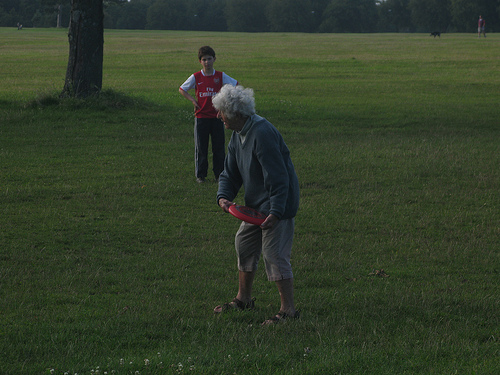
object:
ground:
[1, 32, 492, 375]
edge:
[264, 274, 294, 286]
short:
[233, 213, 294, 284]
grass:
[297, 32, 499, 163]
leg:
[259, 220, 301, 326]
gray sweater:
[216, 121, 296, 221]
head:
[210, 82, 259, 132]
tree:
[58, 1, 107, 100]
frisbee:
[223, 203, 265, 227]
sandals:
[207, 299, 299, 326]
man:
[203, 82, 304, 325]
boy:
[178, 45, 241, 184]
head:
[195, 42, 218, 71]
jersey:
[179, 71, 240, 118]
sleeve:
[179, 73, 197, 92]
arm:
[175, 73, 200, 109]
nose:
[214, 109, 220, 120]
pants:
[191, 115, 225, 178]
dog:
[12, 20, 21, 29]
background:
[6, 3, 499, 48]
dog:
[428, 27, 441, 37]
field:
[318, 24, 498, 97]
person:
[473, 10, 488, 38]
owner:
[475, 16, 488, 40]